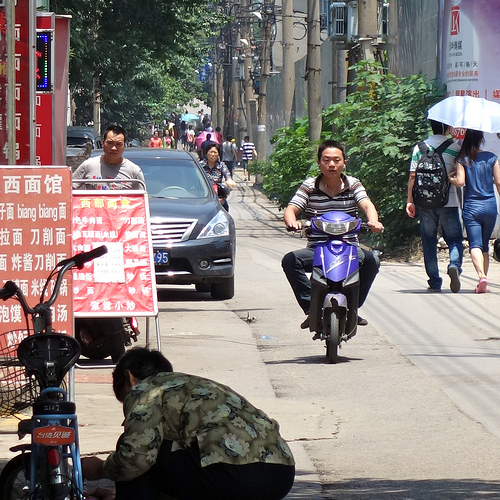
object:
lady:
[97, 347, 301, 498]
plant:
[306, 46, 441, 258]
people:
[401, 112, 498, 302]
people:
[139, 98, 269, 208]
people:
[61, 125, 146, 205]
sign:
[67, 181, 163, 319]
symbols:
[0, 173, 68, 195]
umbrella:
[423, 91, 499, 133]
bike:
[0, 243, 109, 498]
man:
[275, 137, 388, 332]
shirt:
[284, 170, 373, 251]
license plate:
[153, 251, 167, 266]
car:
[119, 141, 238, 298]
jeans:
[417, 205, 464, 290]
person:
[448, 128, 499, 292]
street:
[4, 160, 498, 498]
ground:
[0, 134, 499, 498]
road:
[190, 143, 498, 497]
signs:
[1, 158, 75, 371]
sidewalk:
[1, 128, 324, 499]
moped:
[283, 209, 388, 365]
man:
[407, 116, 467, 292]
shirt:
[96, 364, 299, 486]